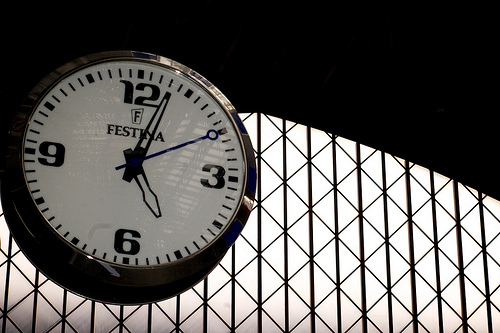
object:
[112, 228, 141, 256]
number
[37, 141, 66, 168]
number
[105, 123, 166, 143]
word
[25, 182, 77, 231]
lines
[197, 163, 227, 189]
numbers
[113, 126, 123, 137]
letters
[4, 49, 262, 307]
clock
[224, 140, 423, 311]
grate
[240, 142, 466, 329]
grate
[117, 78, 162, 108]
number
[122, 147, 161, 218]
hand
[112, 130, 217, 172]
hand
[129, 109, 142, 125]
letter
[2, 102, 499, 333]
lines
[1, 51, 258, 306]
frame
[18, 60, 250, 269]
clock face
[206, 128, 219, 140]
circle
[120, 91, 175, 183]
hand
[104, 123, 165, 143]
name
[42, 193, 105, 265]
minute lines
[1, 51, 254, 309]
rim